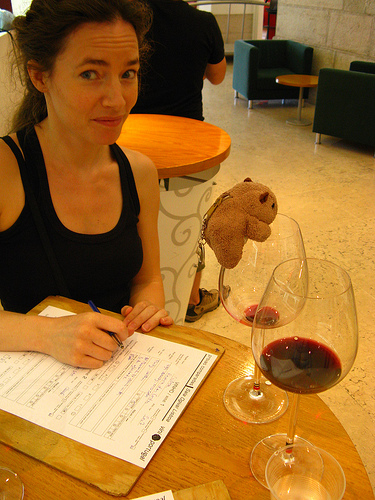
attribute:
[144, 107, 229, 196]
table — round 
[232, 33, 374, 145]
chairs — green 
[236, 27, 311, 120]
chair — blue 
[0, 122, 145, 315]
tank top — black 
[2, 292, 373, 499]
round table — round 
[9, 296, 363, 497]
table — round 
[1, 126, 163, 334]
tank top — black 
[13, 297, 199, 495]
board — brown 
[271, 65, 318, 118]
table — small , wooden 